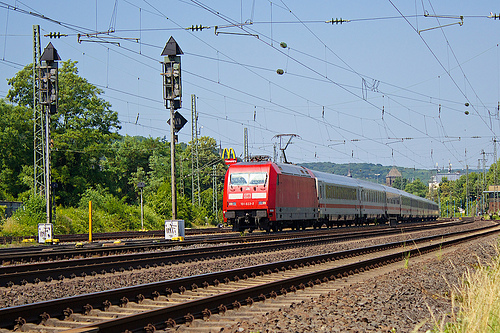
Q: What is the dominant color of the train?
A: Silver.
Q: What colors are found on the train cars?
A: Red and Silver.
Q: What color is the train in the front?
A: Red.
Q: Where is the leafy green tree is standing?
A: Next to the tracks.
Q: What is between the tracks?
A: Gravel.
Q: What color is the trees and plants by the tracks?
A: Green.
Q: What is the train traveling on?
A: Tracks.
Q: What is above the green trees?
A: Wires.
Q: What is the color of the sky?
A: Blue.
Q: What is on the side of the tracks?
A: Gravel and rocks.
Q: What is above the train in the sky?
A: Wires.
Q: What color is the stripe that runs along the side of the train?
A: Red.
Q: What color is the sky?
A: Blue.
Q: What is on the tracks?
A: Train.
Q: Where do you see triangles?
A: Top of poles.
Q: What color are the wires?
A: Black.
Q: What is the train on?
A: Railroad Tracks.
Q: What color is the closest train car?
A: Red.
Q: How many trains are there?
A: One.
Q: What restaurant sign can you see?
A: McDonald's.